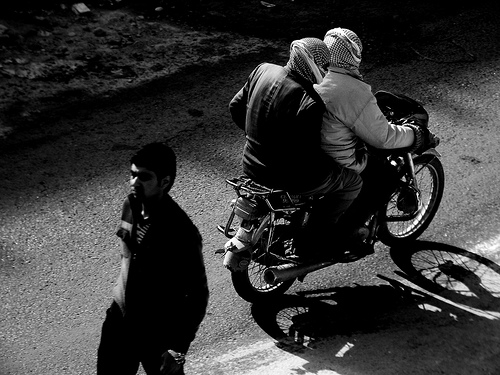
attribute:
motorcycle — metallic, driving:
[214, 90, 444, 303]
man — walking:
[97, 141, 215, 374]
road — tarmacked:
[0, 34, 499, 372]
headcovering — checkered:
[284, 27, 367, 86]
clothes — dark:
[230, 62, 366, 242]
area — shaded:
[8, 34, 234, 135]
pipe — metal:
[256, 262, 309, 284]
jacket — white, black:
[317, 73, 414, 186]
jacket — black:
[225, 61, 336, 198]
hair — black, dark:
[131, 141, 180, 177]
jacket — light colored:
[309, 69, 401, 183]